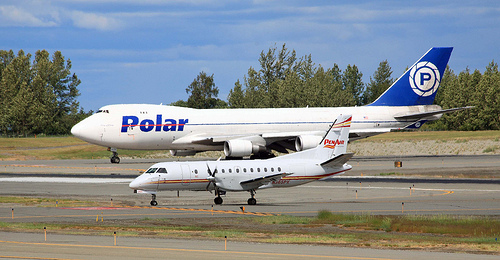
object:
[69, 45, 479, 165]
airplane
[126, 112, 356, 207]
airplane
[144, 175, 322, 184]
stripe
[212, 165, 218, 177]
propeller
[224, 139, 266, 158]
jet engine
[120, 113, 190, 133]
logo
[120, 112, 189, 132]
polar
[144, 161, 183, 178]
cockpit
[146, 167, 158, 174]
window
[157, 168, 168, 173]
window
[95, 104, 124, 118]
cockpit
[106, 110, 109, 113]
window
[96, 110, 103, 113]
window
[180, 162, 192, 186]
door hatch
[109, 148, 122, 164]
landing gear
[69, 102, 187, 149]
front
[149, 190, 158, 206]
landing gear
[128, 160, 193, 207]
front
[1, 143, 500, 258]
ground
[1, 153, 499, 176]
runway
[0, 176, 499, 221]
runway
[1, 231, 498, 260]
air strip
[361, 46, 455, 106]
tail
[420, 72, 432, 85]
letter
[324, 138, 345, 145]
writing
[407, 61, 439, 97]
design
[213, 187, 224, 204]
landing gear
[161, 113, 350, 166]
back